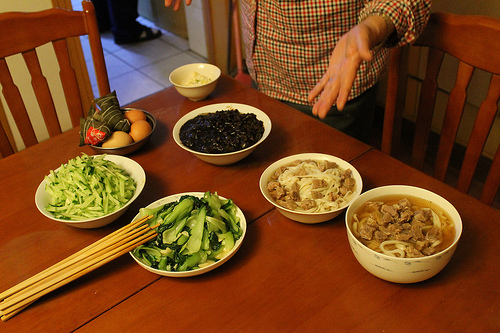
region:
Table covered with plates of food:
[4, 3, 492, 326]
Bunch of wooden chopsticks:
[0, 205, 173, 332]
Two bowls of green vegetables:
[30, 150, 246, 301]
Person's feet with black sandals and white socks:
[103, 9, 170, 55]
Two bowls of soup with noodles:
[257, 147, 468, 289]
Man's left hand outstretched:
[284, 22, 413, 139]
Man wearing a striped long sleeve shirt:
[225, 0, 440, 112]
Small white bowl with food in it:
[160, 52, 226, 98]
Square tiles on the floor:
[115, 49, 161, 86]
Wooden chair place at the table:
[377, 4, 499, 216]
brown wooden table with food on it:
[0, 71, 497, 331]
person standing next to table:
[156, 0, 427, 145]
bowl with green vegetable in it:
[125, 190, 240, 275]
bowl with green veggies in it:
[30, 150, 140, 225]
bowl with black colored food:
[170, 100, 270, 160]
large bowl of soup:
[345, 180, 460, 280]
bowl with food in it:
[255, 145, 360, 220]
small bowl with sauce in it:
[165, 56, 215, 96]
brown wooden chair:
[1, 0, 112, 161]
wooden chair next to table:
[375, 6, 497, 202]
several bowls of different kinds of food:
[18, 67, 481, 289]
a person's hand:
[291, 15, 389, 135]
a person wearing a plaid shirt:
[238, 12, 408, 94]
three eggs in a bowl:
[117, 103, 156, 146]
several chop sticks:
[10, 205, 150, 315]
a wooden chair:
[3, 11, 113, 129]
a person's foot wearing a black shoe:
[101, 12, 161, 57]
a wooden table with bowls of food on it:
[5, 92, 457, 312]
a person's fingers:
[155, 1, 200, 17]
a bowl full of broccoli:
[122, 182, 254, 280]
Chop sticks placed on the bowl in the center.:
[3, 213, 161, 323]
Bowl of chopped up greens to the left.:
[37, 136, 149, 215]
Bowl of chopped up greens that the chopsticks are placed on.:
[121, 187, 251, 278]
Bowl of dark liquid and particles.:
[170, 100, 273, 160]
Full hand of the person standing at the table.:
[307, 28, 369, 114]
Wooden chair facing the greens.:
[1, 13, 129, 157]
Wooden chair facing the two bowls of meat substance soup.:
[378, 3, 499, 158]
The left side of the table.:
[22, 51, 361, 226]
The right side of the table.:
[72, 141, 495, 332]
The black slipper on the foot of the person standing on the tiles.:
[118, 22, 162, 39]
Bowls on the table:
[33, 81, 450, 325]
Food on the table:
[223, 152, 352, 217]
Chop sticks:
[13, 221, 182, 296]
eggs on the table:
[78, 101, 168, 131]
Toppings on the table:
[49, 87, 416, 309]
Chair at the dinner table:
[381, 13, 496, 193]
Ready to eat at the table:
[110, 45, 456, 311]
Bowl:
[96, 121, 298, 282]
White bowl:
[298, 161, 491, 298]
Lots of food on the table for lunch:
[26, 95, 428, 320]